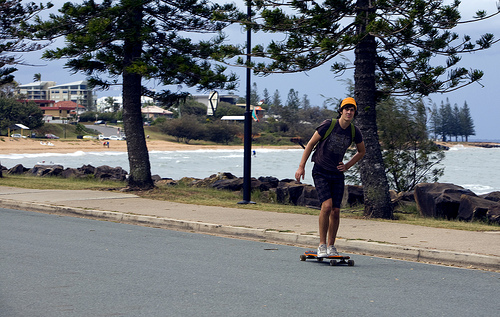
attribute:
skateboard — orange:
[286, 253, 356, 264]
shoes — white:
[318, 244, 339, 255]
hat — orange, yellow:
[342, 96, 359, 106]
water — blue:
[64, 155, 128, 168]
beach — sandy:
[27, 145, 72, 153]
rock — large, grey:
[456, 192, 499, 221]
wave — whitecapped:
[12, 151, 31, 158]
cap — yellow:
[339, 94, 357, 108]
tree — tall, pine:
[123, 4, 158, 187]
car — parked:
[10, 132, 27, 142]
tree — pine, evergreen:
[33, 2, 232, 187]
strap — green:
[327, 115, 337, 141]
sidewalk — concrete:
[99, 192, 278, 235]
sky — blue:
[291, 74, 339, 100]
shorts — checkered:
[314, 164, 348, 203]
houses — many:
[19, 79, 100, 102]